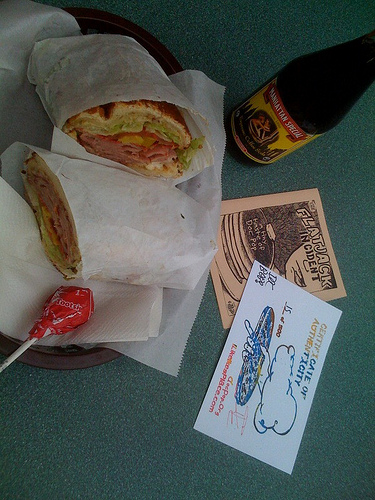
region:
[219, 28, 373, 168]
a dark brown bottle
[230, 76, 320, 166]
a yellow, brown and red label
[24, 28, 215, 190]
half a sandwich wrapped in white paper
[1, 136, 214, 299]
half a sandwich wrapped in white paper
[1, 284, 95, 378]
a sucker wrapped in red paper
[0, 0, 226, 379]
a white paper under sandwiches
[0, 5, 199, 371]
a brown serving basket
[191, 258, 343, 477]
a white piece of paper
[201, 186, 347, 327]
a tan piece of paper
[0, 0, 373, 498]
the table is green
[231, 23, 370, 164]
Bottle of Manhattan Special espresso coffee soda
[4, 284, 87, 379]
red Tootsie Roll pop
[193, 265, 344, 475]
white business card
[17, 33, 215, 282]
sandwich cut in half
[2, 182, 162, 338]
white napkin beside the sandwich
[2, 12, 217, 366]
sandwich and lollipop on a plate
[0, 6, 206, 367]
brown plate with a ham sandwich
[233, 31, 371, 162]
bottle with a yellow label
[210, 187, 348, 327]
brown piece of paper with a cartoon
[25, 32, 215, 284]
two halves of a sandwich wrapped in paper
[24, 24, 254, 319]
a sandwich on a plate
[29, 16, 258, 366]
a sandwich in a basket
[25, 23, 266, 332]
a sandwich wrapped in a paper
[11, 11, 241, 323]
a sandiwch with meat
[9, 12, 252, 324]
a sandwich with lettuce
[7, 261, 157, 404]
a red tootsie pop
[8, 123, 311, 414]
a sandwich laying on napkins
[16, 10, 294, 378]
two halves of a sandwich in a basket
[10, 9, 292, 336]
a sandwich cut into two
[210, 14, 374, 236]
a bottle of drink on the table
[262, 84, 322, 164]
Red label on bottle.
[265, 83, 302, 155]
White writing in red label on bottle.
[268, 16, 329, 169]
Brown bottle on table.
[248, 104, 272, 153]
Picture of two people on bottle.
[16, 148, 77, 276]
Half of sandwich on plate.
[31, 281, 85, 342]
Red sucker wrapper on sucker.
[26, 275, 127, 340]
Sucker sitting on white napkin.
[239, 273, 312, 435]
White certificate on table.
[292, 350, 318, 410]
Blue writing on certificate.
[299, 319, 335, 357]
Yellow writing on certificate.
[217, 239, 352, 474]
white card on table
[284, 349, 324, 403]
blue letters on card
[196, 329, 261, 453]
red letters on card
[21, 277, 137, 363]
sucker wrapper is red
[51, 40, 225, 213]
half of a sandwich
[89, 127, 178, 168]
ham in the sandwich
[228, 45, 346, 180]
the bottle is brown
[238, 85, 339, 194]
yellow label on bottle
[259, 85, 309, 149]
white letters on label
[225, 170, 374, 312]
orange card next to white card